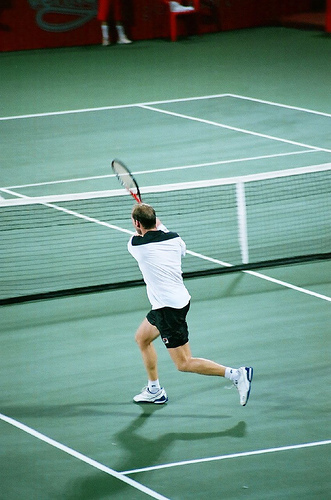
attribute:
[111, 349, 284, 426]
shoes — white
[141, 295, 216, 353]
shorts — white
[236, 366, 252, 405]
sneaker — white, blue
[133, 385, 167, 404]
sneaker — white, blue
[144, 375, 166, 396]
sock — black, white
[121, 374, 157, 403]
lace — white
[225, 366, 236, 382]
sock — black, white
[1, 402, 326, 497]
paint — white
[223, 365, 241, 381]
sock — white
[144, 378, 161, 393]
sock — white